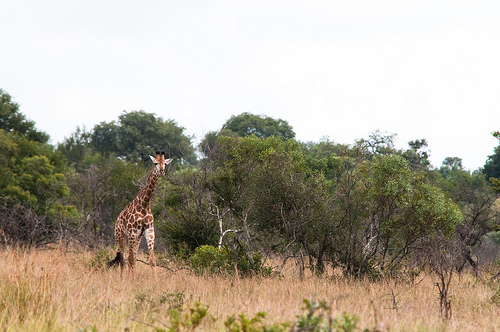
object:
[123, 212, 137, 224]
skin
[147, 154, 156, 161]
ear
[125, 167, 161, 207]
neck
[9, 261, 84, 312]
grass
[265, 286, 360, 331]
plants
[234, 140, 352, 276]
trees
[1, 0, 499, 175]
sky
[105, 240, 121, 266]
tail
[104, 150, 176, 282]
giraffe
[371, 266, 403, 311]
twigs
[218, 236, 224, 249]
bark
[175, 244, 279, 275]
bush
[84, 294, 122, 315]
weeds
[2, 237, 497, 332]
savannah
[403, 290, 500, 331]
ground